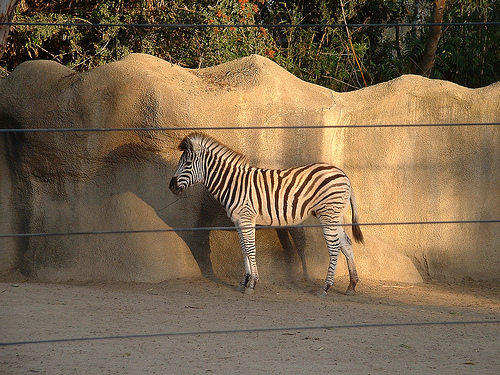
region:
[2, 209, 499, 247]
Wire from the fence.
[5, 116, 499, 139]
A fence wire.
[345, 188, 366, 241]
A zebra tail.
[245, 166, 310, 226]
Black and white stripes.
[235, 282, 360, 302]
All four zebra hooves.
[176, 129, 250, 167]
The mohawk hair of the zebra.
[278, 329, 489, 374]
The leaves on the dirt ground.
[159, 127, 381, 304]
A zebra standing in the dirt.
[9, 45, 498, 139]
Humps in the cement wall.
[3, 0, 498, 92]
Trees behind the wall.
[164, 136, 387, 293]
zebra is black and white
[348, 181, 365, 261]
zebra has long tail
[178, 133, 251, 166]
zebra has long mane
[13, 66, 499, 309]
rock structure behind zebra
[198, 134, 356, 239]
zebra has vertical stripes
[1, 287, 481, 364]
ground is sandy under zebra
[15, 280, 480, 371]
ground is bare under zebra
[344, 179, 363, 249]
zebra has black and white tail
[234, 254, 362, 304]
zebra has dark hoofs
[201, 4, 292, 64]
flowering tree behind rock structure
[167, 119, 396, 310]
black and white striped zebra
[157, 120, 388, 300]
zebra near a wall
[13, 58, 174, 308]
fake rock wall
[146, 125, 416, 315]
zebra standing sidways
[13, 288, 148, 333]
light brown dirt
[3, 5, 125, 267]
fence in front of bushes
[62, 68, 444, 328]
zebra in an exhibit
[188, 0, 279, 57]
shrub with dark orange flowers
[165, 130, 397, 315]
zebra standing on dirt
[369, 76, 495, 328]
tan faux rock wall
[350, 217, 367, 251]
Zebra has black hair on tail.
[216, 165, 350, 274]
Zebra is black and white.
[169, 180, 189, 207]
Zebra has black nose.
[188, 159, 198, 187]
Zebra has dark eye.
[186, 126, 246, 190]
Zebra has black and white mane.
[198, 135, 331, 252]
Zebra is covered in stripes.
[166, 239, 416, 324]
Zebra is standing in dirt.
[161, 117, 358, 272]
Zebra is standing in front of wall.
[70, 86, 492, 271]
Large rock wall behind zebra.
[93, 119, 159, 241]
Shadow of zebra on wall.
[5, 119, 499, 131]
metal wire fence line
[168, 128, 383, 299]
black and white zebra behind wire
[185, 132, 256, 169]
mane is black and white striped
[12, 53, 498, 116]
wavy top of rock wall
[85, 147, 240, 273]
zebra shadow on wall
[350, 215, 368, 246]
tip of tail is black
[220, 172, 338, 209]
black and white stripes on zebra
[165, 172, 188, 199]
zebra has black muzzle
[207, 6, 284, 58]
red flowers on tree in background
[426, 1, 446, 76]
brown tree trunk